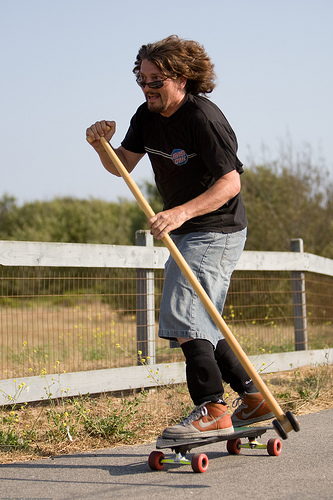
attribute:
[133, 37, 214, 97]
hair — brown, blowing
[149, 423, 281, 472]
skateboard — old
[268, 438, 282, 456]
wheel — red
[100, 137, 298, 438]
mallet — long, used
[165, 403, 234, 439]
shoe — orange, old, red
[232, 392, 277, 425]
shoe — orange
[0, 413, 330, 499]
road — paved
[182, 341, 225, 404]
ankle pad — black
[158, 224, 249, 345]
shorts — blue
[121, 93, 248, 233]
t-shirt — black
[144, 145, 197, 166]
logo — white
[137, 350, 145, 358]
flower — yellow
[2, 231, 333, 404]
fence — metal, wood, gray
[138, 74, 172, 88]
sunglasses — black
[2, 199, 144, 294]
shrub — growing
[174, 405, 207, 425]
shoelace — white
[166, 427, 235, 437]
sole — white